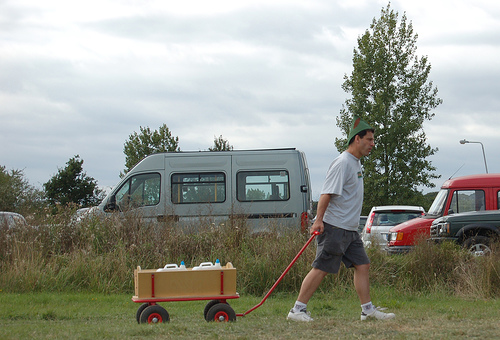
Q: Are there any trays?
A: No, there are no trays.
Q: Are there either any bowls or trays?
A: No, there are no trays or bowls.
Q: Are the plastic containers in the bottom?
A: Yes, the containers are in the bottom of the image.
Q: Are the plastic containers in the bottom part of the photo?
A: Yes, the containers are in the bottom of the image.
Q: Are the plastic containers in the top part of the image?
A: No, the containers are in the bottom of the image.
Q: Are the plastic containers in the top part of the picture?
A: No, the containers are in the bottom of the image.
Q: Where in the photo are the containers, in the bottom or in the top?
A: The containers are in the bottom of the image.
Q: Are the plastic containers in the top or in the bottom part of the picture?
A: The containers are in the bottom of the image.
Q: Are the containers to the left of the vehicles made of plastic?
A: Yes, the containers are made of plastic.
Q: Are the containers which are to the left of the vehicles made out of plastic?
A: Yes, the containers are made of plastic.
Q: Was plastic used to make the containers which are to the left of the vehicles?
A: Yes, the containers are made of plastic.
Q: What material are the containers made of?
A: The containers are made of plastic.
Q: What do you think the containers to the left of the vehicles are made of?
A: The containers are made of plastic.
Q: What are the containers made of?
A: The containers are made of plastic.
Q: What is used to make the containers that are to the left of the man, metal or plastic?
A: The containers are made of plastic.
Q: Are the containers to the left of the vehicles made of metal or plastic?
A: The containers are made of plastic.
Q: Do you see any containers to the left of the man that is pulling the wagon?
A: Yes, there are containers to the left of the man.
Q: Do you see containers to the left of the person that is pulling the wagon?
A: Yes, there are containers to the left of the man.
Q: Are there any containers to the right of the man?
A: No, the containers are to the left of the man.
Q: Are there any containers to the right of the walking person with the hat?
A: No, the containers are to the left of the man.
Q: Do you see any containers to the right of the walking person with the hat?
A: No, the containers are to the left of the man.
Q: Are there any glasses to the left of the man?
A: No, there are containers to the left of the man.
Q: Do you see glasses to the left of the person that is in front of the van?
A: No, there are containers to the left of the man.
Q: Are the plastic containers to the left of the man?
A: Yes, the containers are to the left of the man.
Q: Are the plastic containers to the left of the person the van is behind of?
A: Yes, the containers are to the left of the man.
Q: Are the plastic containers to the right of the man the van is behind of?
A: No, the containers are to the left of the man.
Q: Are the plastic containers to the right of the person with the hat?
A: No, the containers are to the left of the man.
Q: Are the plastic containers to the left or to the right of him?
A: The containers are to the left of the man.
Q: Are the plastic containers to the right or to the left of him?
A: The containers are to the left of the man.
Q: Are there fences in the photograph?
A: No, there are no fences.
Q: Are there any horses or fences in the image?
A: No, there are no fences or horses.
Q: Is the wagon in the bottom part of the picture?
A: Yes, the wagon is in the bottom of the image.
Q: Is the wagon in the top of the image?
A: No, the wagon is in the bottom of the image.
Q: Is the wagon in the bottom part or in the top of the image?
A: The wagon is in the bottom of the image.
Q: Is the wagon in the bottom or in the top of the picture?
A: The wagon is in the bottom of the image.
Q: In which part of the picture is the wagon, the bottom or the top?
A: The wagon is in the bottom of the image.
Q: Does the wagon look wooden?
A: Yes, the wagon is wooden.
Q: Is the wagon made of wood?
A: Yes, the wagon is made of wood.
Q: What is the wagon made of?
A: The wagon is made of wood.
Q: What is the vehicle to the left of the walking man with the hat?
A: The vehicle is a wagon.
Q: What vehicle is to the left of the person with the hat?
A: The vehicle is a wagon.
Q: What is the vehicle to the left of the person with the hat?
A: The vehicle is a wagon.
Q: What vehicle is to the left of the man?
A: The vehicle is a wagon.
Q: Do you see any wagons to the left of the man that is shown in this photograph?
A: Yes, there is a wagon to the left of the man.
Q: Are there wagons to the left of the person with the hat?
A: Yes, there is a wagon to the left of the man.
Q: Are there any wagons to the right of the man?
A: No, the wagon is to the left of the man.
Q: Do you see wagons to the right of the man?
A: No, the wagon is to the left of the man.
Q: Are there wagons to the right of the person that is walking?
A: No, the wagon is to the left of the man.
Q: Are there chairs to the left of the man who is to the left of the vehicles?
A: No, there is a wagon to the left of the man.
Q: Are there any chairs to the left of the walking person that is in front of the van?
A: No, there is a wagon to the left of the man.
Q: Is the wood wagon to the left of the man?
A: Yes, the wagon is to the left of the man.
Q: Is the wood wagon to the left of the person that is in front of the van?
A: Yes, the wagon is to the left of the man.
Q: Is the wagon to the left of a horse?
A: No, the wagon is to the left of the man.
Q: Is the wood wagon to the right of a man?
A: No, the wagon is to the left of a man.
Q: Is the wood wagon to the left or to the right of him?
A: The wagon is to the left of the man.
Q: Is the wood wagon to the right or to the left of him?
A: The wagon is to the left of the man.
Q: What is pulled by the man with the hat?
A: The wagon is pulled by the man.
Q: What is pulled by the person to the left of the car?
A: The wagon is pulled by the man.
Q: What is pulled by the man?
A: The wagon is pulled by the man.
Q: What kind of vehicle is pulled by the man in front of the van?
A: The vehicle is a wagon.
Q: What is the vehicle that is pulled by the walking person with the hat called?
A: The vehicle is a wagon.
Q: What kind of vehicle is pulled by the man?
A: The vehicle is a wagon.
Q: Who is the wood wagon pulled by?
A: The wagon is pulled by the man.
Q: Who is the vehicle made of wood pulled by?
A: The wagon is pulled by the man.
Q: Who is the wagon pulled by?
A: The wagon is pulled by the man.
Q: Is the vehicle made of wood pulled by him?
A: Yes, the wagon is pulled by the man.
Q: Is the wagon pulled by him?
A: Yes, the wagon is pulled by the man.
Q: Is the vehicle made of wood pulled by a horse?
A: No, the wagon is pulled by the man.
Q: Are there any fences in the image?
A: No, there are no fences.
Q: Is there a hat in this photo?
A: Yes, there is a hat.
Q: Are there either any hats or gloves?
A: Yes, there is a hat.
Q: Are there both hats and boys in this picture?
A: No, there is a hat but no boys.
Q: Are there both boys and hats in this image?
A: No, there is a hat but no boys.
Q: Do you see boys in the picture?
A: No, there are no boys.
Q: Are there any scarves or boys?
A: No, there are no boys or scarves.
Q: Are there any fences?
A: No, there are no fences.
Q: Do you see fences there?
A: No, there are no fences.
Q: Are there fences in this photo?
A: No, there are no fences.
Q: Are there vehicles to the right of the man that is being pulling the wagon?
A: Yes, there are vehicles to the right of the man.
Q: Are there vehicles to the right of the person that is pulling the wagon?
A: Yes, there are vehicles to the right of the man.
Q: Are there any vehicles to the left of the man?
A: No, the vehicles are to the right of the man.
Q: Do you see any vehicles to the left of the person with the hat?
A: No, the vehicles are to the right of the man.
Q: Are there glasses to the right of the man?
A: No, there are vehicles to the right of the man.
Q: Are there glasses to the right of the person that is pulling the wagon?
A: No, there are vehicles to the right of the man.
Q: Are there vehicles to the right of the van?
A: Yes, there are vehicles to the right of the van.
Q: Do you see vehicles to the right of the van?
A: Yes, there are vehicles to the right of the van.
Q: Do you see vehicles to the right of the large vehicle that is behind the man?
A: Yes, there are vehicles to the right of the van.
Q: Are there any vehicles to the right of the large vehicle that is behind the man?
A: Yes, there are vehicles to the right of the van.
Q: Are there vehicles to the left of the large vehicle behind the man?
A: No, the vehicles are to the right of the van.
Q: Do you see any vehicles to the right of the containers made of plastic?
A: Yes, there are vehicles to the right of the containers.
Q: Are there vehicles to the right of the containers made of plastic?
A: Yes, there are vehicles to the right of the containers.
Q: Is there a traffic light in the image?
A: No, there are no traffic lights.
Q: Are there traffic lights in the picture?
A: No, there are no traffic lights.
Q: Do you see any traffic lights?
A: No, there are no traffic lights.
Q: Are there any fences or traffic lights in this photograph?
A: No, there are no traffic lights or fences.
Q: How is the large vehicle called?
A: The vehicle is a van.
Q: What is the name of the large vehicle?
A: The vehicle is a van.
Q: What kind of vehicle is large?
A: The vehicle is a van.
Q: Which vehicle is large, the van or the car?
A: The van is large.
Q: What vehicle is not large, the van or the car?
A: The car is not large.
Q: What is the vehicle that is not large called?
A: The vehicle is a car.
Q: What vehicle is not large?
A: The vehicle is a car.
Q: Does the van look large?
A: Yes, the van is large.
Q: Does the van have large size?
A: Yes, the van is large.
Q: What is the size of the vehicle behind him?
A: The van is large.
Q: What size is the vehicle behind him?
A: The van is large.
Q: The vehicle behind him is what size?
A: The van is large.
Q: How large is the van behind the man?
A: The van is large.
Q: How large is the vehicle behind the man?
A: The van is large.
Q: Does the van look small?
A: No, the van is large.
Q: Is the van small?
A: No, the van is large.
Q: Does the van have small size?
A: No, the van is large.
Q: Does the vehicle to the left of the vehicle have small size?
A: No, the van is large.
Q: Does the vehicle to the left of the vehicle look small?
A: No, the van is large.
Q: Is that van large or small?
A: The van is large.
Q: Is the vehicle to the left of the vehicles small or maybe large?
A: The van is large.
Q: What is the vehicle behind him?
A: The vehicle is a van.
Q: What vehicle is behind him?
A: The vehicle is a van.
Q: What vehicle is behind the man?
A: The vehicle is a van.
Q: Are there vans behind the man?
A: Yes, there is a van behind the man.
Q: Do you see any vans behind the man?
A: Yes, there is a van behind the man.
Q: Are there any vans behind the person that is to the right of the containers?
A: Yes, there is a van behind the man.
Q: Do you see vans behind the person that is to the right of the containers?
A: Yes, there is a van behind the man.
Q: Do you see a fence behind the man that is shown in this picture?
A: No, there is a van behind the man.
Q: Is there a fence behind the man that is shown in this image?
A: No, there is a van behind the man.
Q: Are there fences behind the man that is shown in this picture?
A: No, there is a van behind the man.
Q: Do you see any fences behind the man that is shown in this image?
A: No, there is a van behind the man.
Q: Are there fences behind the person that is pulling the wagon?
A: No, there is a van behind the man.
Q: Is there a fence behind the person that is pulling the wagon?
A: No, there is a van behind the man.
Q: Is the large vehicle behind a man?
A: Yes, the van is behind a man.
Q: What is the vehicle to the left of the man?
A: The vehicle is a van.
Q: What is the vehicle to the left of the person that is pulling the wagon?
A: The vehicle is a van.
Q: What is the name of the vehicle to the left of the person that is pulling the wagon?
A: The vehicle is a van.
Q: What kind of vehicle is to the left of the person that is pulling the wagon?
A: The vehicle is a van.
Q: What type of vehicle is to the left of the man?
A: The vehicle is a van.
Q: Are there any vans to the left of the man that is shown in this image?
A: Yes, there is a van to the left of the man.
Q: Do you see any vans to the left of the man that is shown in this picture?
A: Yes, there is a van to the left of the man.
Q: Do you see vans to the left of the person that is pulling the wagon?
A: Yes, there is a van to the left of the man.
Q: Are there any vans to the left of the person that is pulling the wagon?
A: Yes, there is a van to the left of the man.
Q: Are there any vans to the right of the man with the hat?
A: No, the van is to the left of the man.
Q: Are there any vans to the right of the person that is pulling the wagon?
A: No, the van is to the left of the man.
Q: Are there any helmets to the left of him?
A: No, there is a van to the left of the man.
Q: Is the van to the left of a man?
A: Yes, the van is to the left of a man.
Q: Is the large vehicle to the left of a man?
A: Yes, the van is to the left of a man.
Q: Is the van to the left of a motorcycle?
A: No, the van is to the left of a man.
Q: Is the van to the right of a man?
A: No, the van is to the left of a man.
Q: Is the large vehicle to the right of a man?
A: No, the van is to the left of a man.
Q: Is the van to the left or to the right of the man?
A: The van is to the left of the man.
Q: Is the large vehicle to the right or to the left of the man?
A: The van is to the left of the man.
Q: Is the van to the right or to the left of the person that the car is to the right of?
A: The van is to the left of the man.